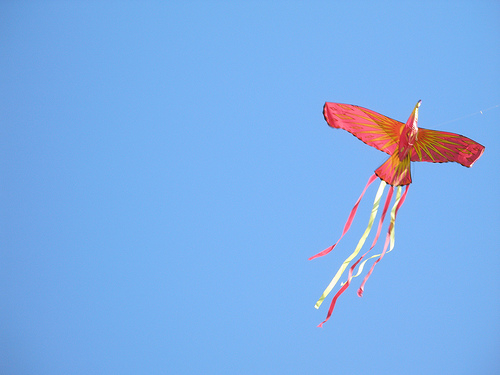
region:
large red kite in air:
[311, 85, 498, 179]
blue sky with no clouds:
[21, 19, 79, 69]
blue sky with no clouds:
[38, 136, 115, 210]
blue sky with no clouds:
[31, 203, 89, 258]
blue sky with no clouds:
[91, 295, 145, 339]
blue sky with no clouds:
[175, 293, 255, 350]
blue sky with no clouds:
[379, 289, 433, 333]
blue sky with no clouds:
[128, 153, 209, 231]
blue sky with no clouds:
[203, 61, 270, 132]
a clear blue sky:
[0, 0, 499, 373]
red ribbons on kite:
[304, 174, 412, 328]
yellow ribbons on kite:
[303, 173, 413, 331]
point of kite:
[410, 92, 427, 109]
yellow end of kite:
[411, 94, 422, 115]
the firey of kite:
[318, 99, 483, 184]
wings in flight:
[321, 98, 486, 168]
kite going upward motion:
[307, 89, 492, 328]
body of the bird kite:
[396, 112, 416, 159]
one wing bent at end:
[462, 132, 484, 172]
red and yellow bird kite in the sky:
[290, 71, 486, 331]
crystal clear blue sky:
[26, 101, 216, 321]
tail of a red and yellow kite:
[306, 155, 426, 326]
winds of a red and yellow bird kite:
[311, 92, 481, 192]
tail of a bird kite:
[366, 150, 421, 210]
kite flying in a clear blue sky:
[280, 40, 485, 341]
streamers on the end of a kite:
[310, 180, 418, 328]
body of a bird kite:
[371, 85, 422, 195]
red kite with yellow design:
[298, 78, 490, 194]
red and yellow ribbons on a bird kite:
[301, 158, 416, 323]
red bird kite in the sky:
[320, 79, 491, 185]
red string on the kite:
[308, 189, 348, 266]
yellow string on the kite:
[307, 275, 329, 314]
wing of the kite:
[314, 90, 381, 157]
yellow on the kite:
[377, 120, 396, 147]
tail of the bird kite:
[372, 163, 411, 187]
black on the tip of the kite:
[320, 104, 327, 122]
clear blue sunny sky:
[125, 233, 200, 325]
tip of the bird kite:
[411, 95, 425, 107]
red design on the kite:
[460, 141, 476, 159]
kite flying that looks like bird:
[288, 66, 488, 324]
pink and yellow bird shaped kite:
[302, 87, 489, 334]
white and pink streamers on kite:
[305, 172, 415, 327]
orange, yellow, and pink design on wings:
[417, 132, 469, 163]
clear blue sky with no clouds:
[36, 133, 207, 302]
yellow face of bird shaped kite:
[403, 92, 443, 142]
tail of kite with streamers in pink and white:
[306, 152, 426, 333]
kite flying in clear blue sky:
[108, 40, 491, 350]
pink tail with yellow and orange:
[371, 152, 418, 192]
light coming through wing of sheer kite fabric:
[314, 90, 400, 166]